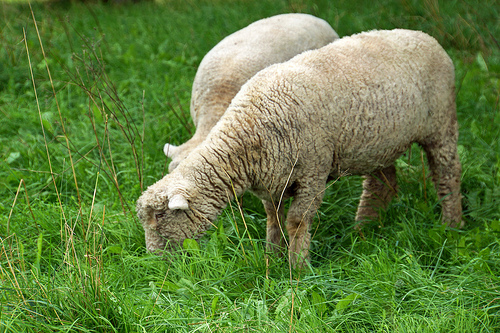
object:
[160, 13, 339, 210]
sheep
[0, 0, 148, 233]
grass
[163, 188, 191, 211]
ear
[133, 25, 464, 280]
sheep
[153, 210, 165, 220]
eye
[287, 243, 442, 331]
grass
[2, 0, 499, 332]
field